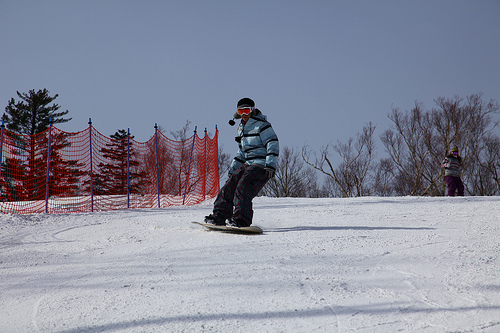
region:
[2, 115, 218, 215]
orange plastic snow fence to the left of snowboarder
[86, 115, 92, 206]
blue post supporting snow fence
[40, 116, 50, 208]
post next to post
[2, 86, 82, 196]
pine tree behind snow fence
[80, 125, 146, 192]
pine tree to the right of pine tree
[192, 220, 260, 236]
snowboard under snowboarder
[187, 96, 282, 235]
snowboarder is snowboarding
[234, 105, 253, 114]
snowboarder wearing red goggles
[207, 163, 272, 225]
snowboarder wearing black snow pants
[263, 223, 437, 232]
snowboarder casts shadow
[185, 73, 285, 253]
person snowboarding in snow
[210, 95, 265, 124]
red goggles on snowboarder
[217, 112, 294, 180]
blue jacket on snowboarder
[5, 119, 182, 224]
red mesh fence on hill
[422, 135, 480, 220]
snowboarder on a snow covered hill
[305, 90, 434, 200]
bare trees on a snow covered hill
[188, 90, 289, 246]
snowboarder in winter clothing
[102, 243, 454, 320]
snow on a hill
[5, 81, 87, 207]
evergreen tree on a snow covered hill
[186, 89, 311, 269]
snowboarder going down hill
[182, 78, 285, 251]
snowboarder on a clear day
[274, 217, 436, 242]
shadow of a snowboarder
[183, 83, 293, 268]
woman on a snowboard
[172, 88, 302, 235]
girl on a snowboard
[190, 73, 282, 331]
lady on a snowboard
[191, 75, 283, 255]
person on a snowboard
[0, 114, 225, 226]
snow fence on the left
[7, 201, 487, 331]
a packed snow surface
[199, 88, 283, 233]
girl in bulky snow pants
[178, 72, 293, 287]
girl facing left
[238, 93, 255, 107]
Black helmet in the photo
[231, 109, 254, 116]
Goggles in the photo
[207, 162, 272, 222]
Black pants in the photo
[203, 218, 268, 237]
Skate board in the photo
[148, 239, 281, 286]
Ice covered surface in the photo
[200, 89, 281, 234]
A person skating in the photo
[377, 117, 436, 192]
Trees in the photo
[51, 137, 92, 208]
Red fence in the photo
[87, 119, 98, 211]
A pole in the photo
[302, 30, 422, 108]
Blue skies in the photo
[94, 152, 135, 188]
red safety net by person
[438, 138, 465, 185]
person wearing black goggles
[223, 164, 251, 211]
person wearing dark pants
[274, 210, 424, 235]
persons shadow on snow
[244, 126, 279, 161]
person wearing black jacket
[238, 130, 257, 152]
person wearing silver jacket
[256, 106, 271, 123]
jacket has silver hood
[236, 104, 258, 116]
person has red goggles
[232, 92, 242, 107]
person wearing black het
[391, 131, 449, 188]
bare trees in background